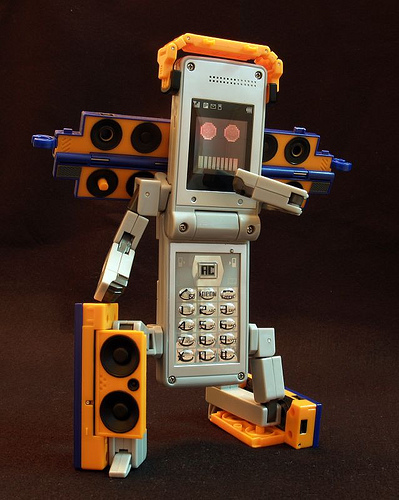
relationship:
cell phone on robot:
[155, 54, 267, 387] [28, 33, 352, 477]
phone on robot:
[154, 53, 270, 389] [28, 33, 352, 477]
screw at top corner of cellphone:
[187, 60, 196, 70] [151, 50, 269, 389]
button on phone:
[163, 283, 221, 319] [168, 54, 289, 423]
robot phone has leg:
[21, 23, 369, 487] [70, 293, 157, 481]